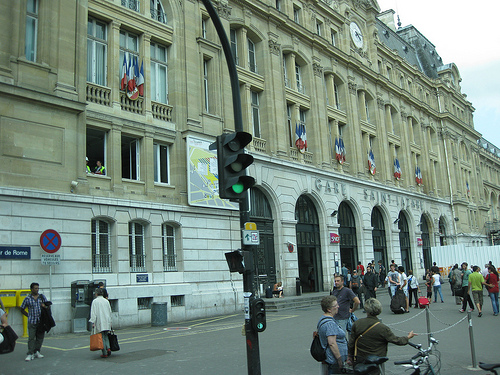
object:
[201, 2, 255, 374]
pole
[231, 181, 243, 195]
light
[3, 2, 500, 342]
building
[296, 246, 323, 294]
doorway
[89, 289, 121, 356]
woman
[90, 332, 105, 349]
bag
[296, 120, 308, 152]
flag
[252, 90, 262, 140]
window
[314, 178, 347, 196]
words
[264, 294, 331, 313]
stairs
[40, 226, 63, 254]
sign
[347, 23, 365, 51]
clock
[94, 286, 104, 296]
head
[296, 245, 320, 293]
door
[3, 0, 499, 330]
wall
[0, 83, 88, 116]
edge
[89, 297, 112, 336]
jacket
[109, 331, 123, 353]
purse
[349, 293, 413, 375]
person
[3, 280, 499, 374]
street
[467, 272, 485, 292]
shirt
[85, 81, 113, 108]
balcony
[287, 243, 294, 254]
map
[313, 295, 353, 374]
people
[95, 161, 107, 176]
worker